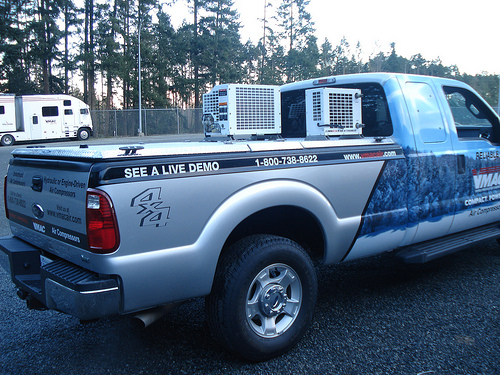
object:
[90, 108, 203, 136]
fence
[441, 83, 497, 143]
window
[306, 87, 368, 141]
machines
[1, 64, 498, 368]
truck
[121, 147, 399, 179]
advertisements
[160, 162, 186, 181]
word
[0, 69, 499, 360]
truck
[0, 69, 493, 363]
truck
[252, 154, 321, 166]
phone number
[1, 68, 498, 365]
truck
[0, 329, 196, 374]
gravel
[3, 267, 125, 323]
bumper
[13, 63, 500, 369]
truck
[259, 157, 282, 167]
800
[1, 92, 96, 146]
rv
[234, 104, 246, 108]
holes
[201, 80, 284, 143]
machine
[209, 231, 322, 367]
tire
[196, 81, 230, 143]
vent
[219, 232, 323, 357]
tire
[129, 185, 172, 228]
symbol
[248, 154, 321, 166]
numbers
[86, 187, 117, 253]
tail light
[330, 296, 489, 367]
gravel